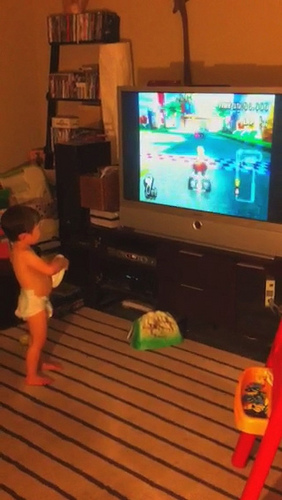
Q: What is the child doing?
A: Watching television.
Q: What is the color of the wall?
A: Brown.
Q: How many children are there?
A: 1.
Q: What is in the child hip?
A: Diaper.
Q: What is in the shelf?
A: Books.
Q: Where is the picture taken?
A: In a living room.